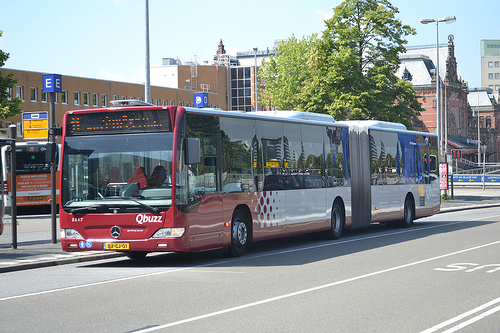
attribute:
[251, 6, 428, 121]
green trees — large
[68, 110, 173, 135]
display — black, digital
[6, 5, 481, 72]
sky — clear, blue, sunny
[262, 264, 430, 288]
stripes — white 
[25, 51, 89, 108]
sign — blue , cube 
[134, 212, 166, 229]
qbuzz — word, white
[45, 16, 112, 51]
sky — clear, blue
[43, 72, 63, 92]
cube — blue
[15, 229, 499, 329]
street — gray , concrete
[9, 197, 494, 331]
road — part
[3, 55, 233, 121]
building — beige, brick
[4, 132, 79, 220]
bus — orange, white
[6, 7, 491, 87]
sky — blue, daytime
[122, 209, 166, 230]
word — qbuzz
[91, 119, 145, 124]
information — orange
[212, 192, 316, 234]
design — red, white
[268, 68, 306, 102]
foliage — green 